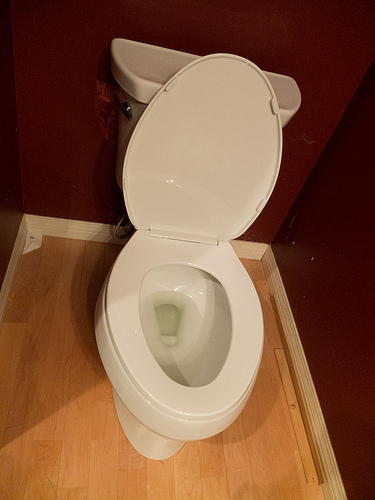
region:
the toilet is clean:
[91, 253, 252, 447]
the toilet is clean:
[92, 159, 358, 480]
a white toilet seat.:
[106, 231, 265, 417]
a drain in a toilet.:
[148, 284, 195, 352]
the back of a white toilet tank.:
[109, 34, 304, 117]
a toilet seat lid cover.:
[121, 50, 285, 242]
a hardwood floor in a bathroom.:
[5, 233, 323, 498]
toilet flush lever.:
[108, 97, 138, 129]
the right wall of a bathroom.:
[269, 66, 371, 496]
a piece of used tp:
[9, 216, 55, 275]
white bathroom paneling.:
[24, 214, 268, 263]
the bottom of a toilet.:
[111, 383, 184, 457]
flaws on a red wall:
[278, 213, 336, 329]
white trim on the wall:
[257, 236, 350, 498]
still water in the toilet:
[143, 273, 200, 362]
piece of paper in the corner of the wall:
[20, 211, 56, 266]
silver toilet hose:
[105, 202, 140, 249]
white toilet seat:
[101, 212, 259, 445]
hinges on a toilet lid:
[141, 212, 243, 265]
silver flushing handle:
[103, 83, 146, 134]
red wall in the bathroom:
[335, 160, 374, 308]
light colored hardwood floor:
[4, 353, 118, 486]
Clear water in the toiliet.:
[151, 293, 192, 345]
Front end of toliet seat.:
[128, 357, 262, 417]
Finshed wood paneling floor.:
[24, 406, 102, 484]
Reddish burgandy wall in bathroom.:
[316, 188, 364, 254]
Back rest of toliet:
[107, 52, 321, 244]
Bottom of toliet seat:
[116, 439, 204, 481]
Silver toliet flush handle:
[101, 83, 136, 129]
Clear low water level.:
[143, 291, 201, 324]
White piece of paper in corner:
[17, 223, 48, 258]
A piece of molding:
[314, 457, 326, 487]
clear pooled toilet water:
[143, 286, 190, 357]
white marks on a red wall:
[289, 212, 327, 313]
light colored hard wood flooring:
[9, 246, 100, 489]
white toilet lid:
[111, 57, 289, 241]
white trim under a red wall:
[256, 240, 352, 498]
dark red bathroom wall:
[321, 241, 374, 418]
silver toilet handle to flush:
[107, 87, 146, 126]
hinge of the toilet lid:
[140, 223, 226, 251]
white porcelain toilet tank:
[86, 23, 306, 237]